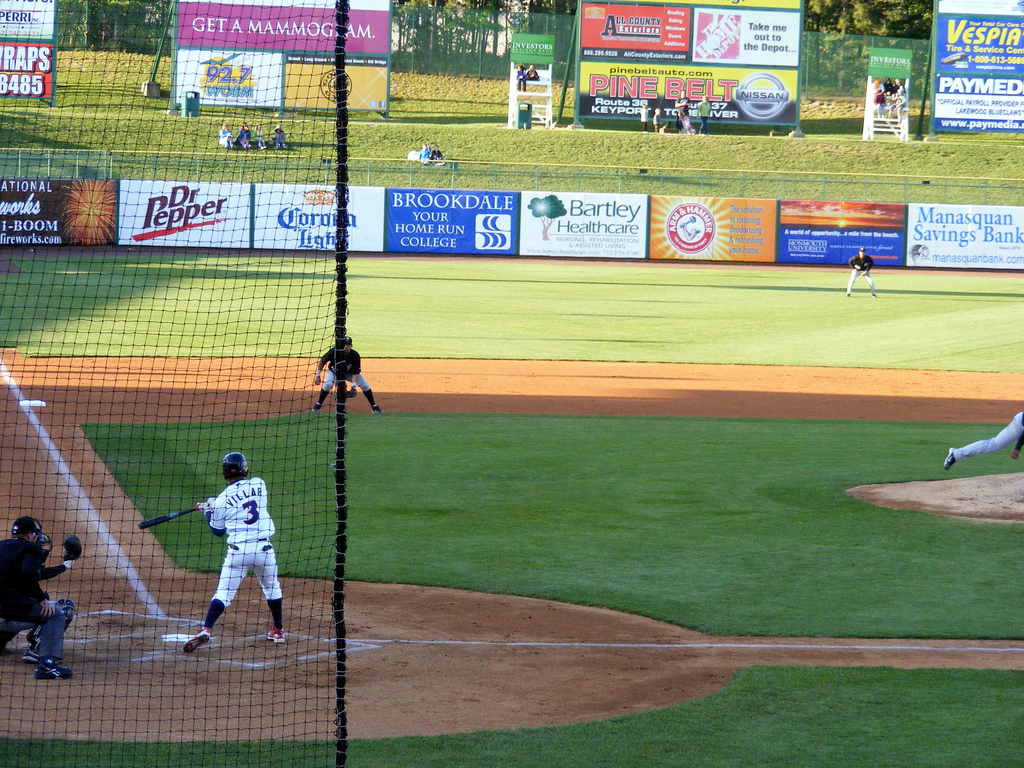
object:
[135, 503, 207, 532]
bat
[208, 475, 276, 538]
jersey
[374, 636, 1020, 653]
line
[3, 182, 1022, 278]
advertisements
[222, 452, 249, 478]
helmet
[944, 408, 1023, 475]
leg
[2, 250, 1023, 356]
grass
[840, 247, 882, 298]
man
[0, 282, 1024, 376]
field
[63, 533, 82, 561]
glove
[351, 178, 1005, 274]
wall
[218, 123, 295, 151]
people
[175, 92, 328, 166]
grassy hill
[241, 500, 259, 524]
number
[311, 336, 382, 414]
dirt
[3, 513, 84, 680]
person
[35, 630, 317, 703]
ground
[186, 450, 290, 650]
catcher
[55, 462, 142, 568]
chalk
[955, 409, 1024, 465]
clothing